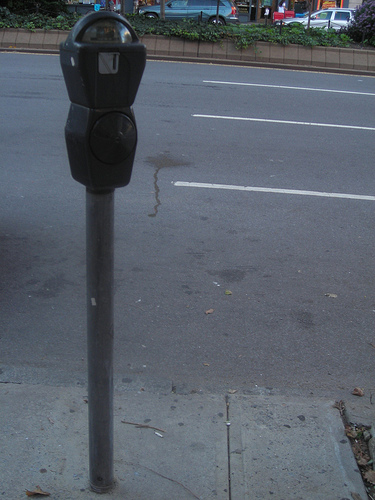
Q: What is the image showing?
A: It is showing a road.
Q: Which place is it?
A: It is a road.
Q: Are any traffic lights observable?
A: No, there are no traffic lights.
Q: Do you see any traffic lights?
A: No, there are no traffic lights.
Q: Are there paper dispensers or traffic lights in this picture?
A: No, there are no traffic lights or paper dispensers.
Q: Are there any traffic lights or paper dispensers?
A: No, there are no traffic lights or paper dispensers.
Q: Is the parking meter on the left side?
A: Yes, the parking meter is on the left of the image.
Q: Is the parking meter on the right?
A: No, the parking meter is on the left of the image.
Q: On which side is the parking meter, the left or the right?
A: The parking meter is on the left of the image.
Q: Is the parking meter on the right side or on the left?
A: The parking meter is on the left of the image.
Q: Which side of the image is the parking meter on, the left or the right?
A: The parking meter is on the left of the image.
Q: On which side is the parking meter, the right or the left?
A: The parking meter is on the left of the image.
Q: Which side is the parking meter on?
A: The parking meter is on the left of the image.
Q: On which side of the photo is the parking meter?
A: The parking meter is on the left of the image.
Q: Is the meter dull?
A: Yes, the meter is dull.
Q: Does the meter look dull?
A: Yes, the meter is dull.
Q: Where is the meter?
A: The meter is on the sidewalk.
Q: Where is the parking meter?
A: The meter is on the sidewalk.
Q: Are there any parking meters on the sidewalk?
A: Yes, there is a parking meter on the sidewalk.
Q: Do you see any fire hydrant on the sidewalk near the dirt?
A: No, there is a parking meter on the sidewalk.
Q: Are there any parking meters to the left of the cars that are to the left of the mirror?
A: Yes, there is a parking meter to the left of the cars.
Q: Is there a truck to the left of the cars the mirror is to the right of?
A: No, there is a parking meter to the left of the cars.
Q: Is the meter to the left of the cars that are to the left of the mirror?
A: Yes, the meter is to the left of the cars.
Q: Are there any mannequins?
A: No, there are no mannequins.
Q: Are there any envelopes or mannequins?
A: No, there are no mannequins or envelopes.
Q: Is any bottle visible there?
A: No, there are no bottles.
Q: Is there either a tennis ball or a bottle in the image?
A: No, there are no bottles or tennis balls.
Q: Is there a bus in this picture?
A: No, there are no buses.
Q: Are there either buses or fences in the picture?
A: No, there are no buses or fences.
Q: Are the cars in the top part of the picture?
A: Yes, the cars are in the top of the image.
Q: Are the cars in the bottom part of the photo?
A: No, the cars are in the top of the image.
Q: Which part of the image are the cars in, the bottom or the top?
A: The cars are in the top of the image.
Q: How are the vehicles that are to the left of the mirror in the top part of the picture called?
A: The vehicles are cars.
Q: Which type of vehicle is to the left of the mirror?
A: The vehicles are cars.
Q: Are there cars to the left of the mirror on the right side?
A: Yes, there are cars to the left of the mirror.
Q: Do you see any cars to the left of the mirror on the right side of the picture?
A: Yes, there are cars to the left of the mirror.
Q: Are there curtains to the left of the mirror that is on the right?
A: No, there are cars to the left of the mirror.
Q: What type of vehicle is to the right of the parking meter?
A: The vehicles are cars.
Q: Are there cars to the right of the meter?
A: Yes, there are cars to the right of the meter.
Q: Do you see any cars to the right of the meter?
A: Yes, there are cars to the right of the meter.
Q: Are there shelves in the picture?
A: No, there are no shelves.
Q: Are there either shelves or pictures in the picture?
A: No, there are no shelves or pictures.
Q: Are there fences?
A: No, there are no fences.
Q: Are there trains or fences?
A: No, there are no fences or trains.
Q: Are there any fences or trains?
A: No, there are no fences or trains.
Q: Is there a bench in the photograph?
A: No, there are no benches.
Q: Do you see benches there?
A: No, there are no benches.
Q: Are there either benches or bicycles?
A: No, there are no benches or bicycles.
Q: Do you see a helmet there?
A: No, there are no helmets.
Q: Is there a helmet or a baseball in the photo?
A: No, there are no helmets or baseballs.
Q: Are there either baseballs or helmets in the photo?
A: No, there are no helmets or baseballs.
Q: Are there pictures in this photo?
A: No, there are no pictures.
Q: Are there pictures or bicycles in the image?
A: No, there are no pictures or bicycles.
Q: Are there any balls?
A: No, there are no balls.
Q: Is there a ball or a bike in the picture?
A: No, there are no balls or bikes.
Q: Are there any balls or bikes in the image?
A: No, there are no balls or bikes.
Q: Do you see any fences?
A: No, there are no fences.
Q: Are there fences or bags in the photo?
A: No, there are no fences or bags.